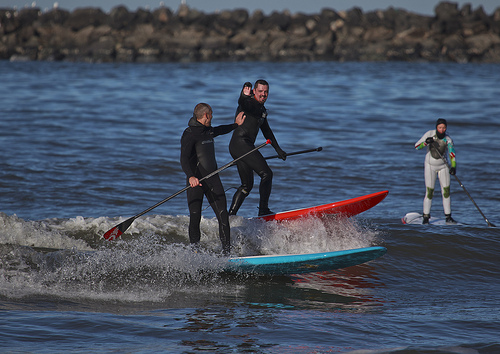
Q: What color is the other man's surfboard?
A: Red.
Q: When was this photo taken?
A: Daytime.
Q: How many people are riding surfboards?
A: Three.